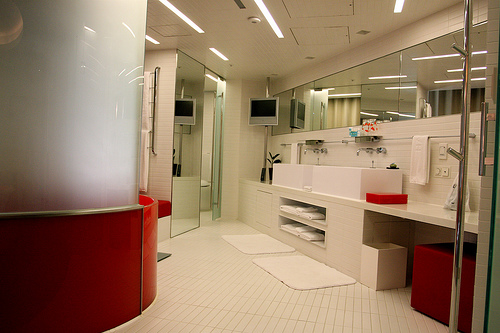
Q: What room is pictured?
A: It is a bathroom.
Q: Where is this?
A: This is at the bathroom.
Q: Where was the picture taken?
A: It was taken at the bathroom.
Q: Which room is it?
A: It is a bathroom.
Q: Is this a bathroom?
A: Yes, it is a bathroom.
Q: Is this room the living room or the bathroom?
A: It is the bathroom.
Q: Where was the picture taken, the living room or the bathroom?
A: It was taken at the bathroom.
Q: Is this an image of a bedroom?
A: No, the picture is showing a bathroom.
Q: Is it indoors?
A: Yes, it is indoors.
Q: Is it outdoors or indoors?
A: It is indoors.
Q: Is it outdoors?
A: No, it is indoors.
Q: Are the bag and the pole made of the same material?
A: No, the bag is made of plastic and the pole is made of metal.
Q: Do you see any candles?
A: No, there are no candles.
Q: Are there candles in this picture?
A: No, there are no candles.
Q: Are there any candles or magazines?
A: No, there are no candles or magazines.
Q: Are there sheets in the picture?
A: No, there are no sheets.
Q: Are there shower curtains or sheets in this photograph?
A: No, there are no sheets or shower curtains.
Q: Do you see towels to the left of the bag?
A: Yes, there are towels to the left of the bag.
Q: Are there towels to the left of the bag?
A: Yes, there are towels to the left of the bag.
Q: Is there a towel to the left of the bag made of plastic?
A: Yes, there are towels to the left of the bag.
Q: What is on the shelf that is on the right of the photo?
A: The towels are on the shelf.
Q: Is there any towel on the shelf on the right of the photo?
A: Yes, there are towels on the shelf.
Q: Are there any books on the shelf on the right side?
A: No, there are towels on the shelf.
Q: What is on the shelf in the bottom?
A: The towels are on the shelf.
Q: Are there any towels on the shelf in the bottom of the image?
A: Yes, there are towels on the shelf.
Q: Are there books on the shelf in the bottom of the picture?
A: No, there are towels on the shelf.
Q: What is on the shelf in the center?
A: The towels are on the shelf.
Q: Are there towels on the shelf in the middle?
A: Yes, there are towels on the shelf.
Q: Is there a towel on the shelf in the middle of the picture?
A: Yes, there are towels on the shelf.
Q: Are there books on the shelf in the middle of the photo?
A: No, there are towels on the shelf.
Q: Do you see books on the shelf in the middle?
A: No, there are towels on the shelf.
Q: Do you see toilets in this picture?
A: No, there are no toilets.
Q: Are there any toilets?
A: No, there are no toilets.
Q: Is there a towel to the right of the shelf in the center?
A: Yes, there are towels to the right of the shelf.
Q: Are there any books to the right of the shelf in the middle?
A: No, there are towels to the right of the shelf.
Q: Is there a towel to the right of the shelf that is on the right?
A: Yes, there are towels to the right of the shelf.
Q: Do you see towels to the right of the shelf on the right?
A: Yes, there are towels to the right of the shelf.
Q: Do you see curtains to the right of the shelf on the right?
A: No, there are towels to the right of the shelf.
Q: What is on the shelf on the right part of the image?
A: The towels are on the shelf.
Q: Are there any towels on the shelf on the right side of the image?
A: Yes, there are towels on the shelf.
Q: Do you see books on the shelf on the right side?
A: No, there are towels on the shelf.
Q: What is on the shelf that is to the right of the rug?
A: The towels are on the shelf.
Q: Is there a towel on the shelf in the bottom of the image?
A: Yes, there are towels on the shelf.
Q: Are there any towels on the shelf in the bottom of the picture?
A: Yes, there are towels on the shelf.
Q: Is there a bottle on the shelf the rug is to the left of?
A: No, there are towels on the shelf.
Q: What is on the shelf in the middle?
A: The towels are on the shelf.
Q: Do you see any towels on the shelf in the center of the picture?
A: Yes, there are towels on the shelf.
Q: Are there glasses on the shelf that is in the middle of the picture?
A: No, there are towels on the shelf.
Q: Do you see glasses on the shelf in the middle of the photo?
A: No, there are towels on the shelf.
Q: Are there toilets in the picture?
A: No, there are no toilets.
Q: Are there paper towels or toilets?
A: No, there are no toilets or paper towels.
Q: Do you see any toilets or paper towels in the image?
A: No, there are no toilets or paper towels.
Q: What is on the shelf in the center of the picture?
A: The towels are on the shelf.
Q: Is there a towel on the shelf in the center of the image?
A: Yes, there are towels on the shelf.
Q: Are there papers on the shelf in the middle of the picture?
A: No, there are towels on the shelf.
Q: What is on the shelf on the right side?
A: The towels are on the shelf.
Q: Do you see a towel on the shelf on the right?
A: Yes, there are towels on the shelf.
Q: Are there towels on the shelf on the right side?
A: Yes, there are towels on the shelf.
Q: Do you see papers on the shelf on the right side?
A: No, there are towels on the shelf.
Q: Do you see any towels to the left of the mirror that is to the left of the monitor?
A: Yes, there are towels to the left of the mirror.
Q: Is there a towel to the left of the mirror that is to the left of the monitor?
A: Yes, there are towels to the left of the mirror.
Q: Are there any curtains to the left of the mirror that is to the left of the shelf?
A: No, there are towels to the left of the mirror.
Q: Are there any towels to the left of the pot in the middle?
A: Yes, there are towels to the left of the pot.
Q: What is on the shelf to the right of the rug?
A: The towels are on the shelf.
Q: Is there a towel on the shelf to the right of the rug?
A: Yes, there are towels on the shelf.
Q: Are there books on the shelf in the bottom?
A: No, there are towels on the shelf.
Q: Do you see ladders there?
A: No, there are no ladders.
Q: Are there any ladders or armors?
A: No, there are no ladders or armors.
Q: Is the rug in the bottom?
A: Yes, the rug is in the bottom of the image.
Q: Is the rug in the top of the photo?
A: No, the rug is in the bottom of the image.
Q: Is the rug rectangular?
A: Yes, the rug is rectangular.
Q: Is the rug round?
A: No, the rug is rectangular.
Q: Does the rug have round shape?
A: No, the rug is rectangular.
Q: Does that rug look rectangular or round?
A: The rug is rectangular.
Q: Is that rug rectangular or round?
A: The rug is rectangular.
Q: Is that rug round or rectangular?
A: The rug is rectangular.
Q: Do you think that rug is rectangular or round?
A: The rug is rectangular.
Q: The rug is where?
A: The rug is in the bathroom.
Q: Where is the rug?
A: The rug is in the bathroom.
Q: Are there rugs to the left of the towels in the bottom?
A: Yes, there is a rug to the left of the towels.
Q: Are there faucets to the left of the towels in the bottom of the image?
A: No, there is a rug to the left of the towels.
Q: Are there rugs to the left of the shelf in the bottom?
A: Yes, there is a rug to the left of the shelf.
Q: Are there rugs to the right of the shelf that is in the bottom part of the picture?
A: No, the rug is to the left of the shelf.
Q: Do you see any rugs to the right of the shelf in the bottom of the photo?
A: No, the rug is to the left of the shelf.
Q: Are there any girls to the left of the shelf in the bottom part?
A: No, there is a rug to the left of the shelf.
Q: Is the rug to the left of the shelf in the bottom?
A: Yes, the rug is to the left of the shelf.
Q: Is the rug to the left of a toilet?
A: No, the rug is to the left of the shelf.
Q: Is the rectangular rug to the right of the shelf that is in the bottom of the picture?
A: No, the rug is to the left of the shelf.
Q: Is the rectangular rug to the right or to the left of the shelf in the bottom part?
A: The rug is to the left of the shelf.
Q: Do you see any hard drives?
A: No, there are no hard drives.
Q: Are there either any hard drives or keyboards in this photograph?
A: No, there are no hard drives or keyboards.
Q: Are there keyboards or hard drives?
A: No, there are no hard drives or keyboards.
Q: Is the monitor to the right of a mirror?
A: Yes, the monitor is to the right of a mirror.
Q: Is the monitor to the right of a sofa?
A: No, the monitor is to the right of a mirror.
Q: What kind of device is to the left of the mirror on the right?
A: The device is a monitor.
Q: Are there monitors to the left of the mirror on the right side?
A: Yes, there is a monitor to the left of the mirror.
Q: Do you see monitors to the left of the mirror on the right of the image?
A: Yes, there is a monitor to the left of the mirror.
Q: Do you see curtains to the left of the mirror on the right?
A: No, there is a monitor to the left of the mirror.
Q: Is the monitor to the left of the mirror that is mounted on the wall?
A: Yes, the monitor is to the left of the mirror.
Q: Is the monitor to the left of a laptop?
A: No, the monitor is to the left of the mirror.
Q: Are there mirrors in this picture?
A: Yes, there is a mirror.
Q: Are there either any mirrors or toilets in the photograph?
A: Yes, there is a mirror.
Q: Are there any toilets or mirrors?
A: Yes, there is a mirror.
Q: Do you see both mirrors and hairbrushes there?
A: No, there is a mirror but no hairbrushes.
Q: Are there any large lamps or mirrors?
A: Yes, there is a large mirror.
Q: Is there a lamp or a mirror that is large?
A: Yes, the mirror is large.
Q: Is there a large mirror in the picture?
A: Yes, there is a large mirror.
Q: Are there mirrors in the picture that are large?
A: Yes, there is a mirror that is large.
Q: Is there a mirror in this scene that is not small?
A: Yes, there is a large mirror.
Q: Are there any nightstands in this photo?
A: No, there are no nightstands.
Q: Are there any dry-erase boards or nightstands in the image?
A: No, there are no nightstands or dry-erase boards.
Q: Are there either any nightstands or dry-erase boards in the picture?
A: No, there are no nightstands or dry-erase boards.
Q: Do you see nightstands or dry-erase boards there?
A: No, there are no nightstands or dry-erase boards.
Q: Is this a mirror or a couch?
A: This is a mirror.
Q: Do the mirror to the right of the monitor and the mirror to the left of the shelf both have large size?
A: Yes, both the mirror and the mirror are large.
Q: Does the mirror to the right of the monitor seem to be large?
A: Yes, the mirror is large.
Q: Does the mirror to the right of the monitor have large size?
A: Yes, the mirror is large.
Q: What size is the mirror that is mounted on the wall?
A: The mirror is large.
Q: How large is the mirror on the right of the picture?
A: The mirror is large.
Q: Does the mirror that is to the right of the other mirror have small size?
A: No, the mirror is large.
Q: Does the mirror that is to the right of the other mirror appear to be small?
A: No, the mirror is large.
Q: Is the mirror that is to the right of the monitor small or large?
A: The mirror is large.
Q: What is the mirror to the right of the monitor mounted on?
A: The mirror is mounted on the wall.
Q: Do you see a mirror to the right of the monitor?
A: Yes, there is a mirror to the right of the monitor.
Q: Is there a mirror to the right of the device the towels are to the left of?
A: Yes, there is a mirror to the right of the monitor.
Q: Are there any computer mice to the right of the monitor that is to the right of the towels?
A: No, there is a mirror to the right of the monitor.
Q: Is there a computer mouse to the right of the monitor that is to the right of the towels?
A: No, there is a mirror to the right of the monitor.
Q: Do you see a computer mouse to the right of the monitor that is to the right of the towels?
A: No, there is a mirror to the right of the monitor.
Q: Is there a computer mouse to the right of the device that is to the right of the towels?
A: No, there is a mirror to the right of the monitor.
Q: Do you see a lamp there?
A: No, there are no lamps.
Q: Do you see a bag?
A: Yes, there is a bag.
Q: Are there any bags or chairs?
A: Yes, there is a bag.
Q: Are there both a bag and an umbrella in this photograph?
A: No, there is a bag but no umbrellas.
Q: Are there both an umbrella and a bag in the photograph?
A: No, there is a bag but no umbrellas.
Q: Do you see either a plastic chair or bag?
A: Yes, there is a plastic bag.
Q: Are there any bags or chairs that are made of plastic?
A: Yes, the bag is made of plastic.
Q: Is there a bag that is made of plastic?
A: Yes, there is a bag that is made of plastic.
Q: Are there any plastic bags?
A: Yes, there is a bag that is made of plastic.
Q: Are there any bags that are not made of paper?
A: Yes, there is a bag that is made of plastic.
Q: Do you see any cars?
A: No, there are no cars.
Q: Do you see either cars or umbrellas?
A: No, there are no cars or umbrellas.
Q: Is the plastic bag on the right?
A: Yes, the bag is on the right of the image.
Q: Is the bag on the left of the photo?
A: No, the bag is on the right of the image.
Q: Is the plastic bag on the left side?
A: No, the bag is on the right of the image.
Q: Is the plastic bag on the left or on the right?
A: The bag is on the right of the image.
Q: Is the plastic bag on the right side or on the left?
A: The bag is on the right of the image.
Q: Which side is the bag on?
A: The bag is on the right of the image.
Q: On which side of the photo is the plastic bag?
A: The bag is on the right of the image.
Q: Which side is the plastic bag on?
A: The bag is on the right of the image.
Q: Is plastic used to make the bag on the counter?
A: Yes, the bag is made of plastic.